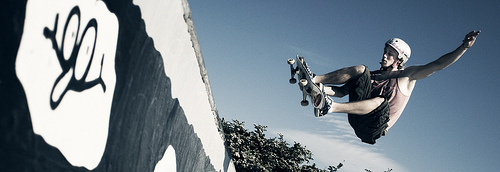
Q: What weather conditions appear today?
A: It is clear.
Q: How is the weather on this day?
A: It is clear.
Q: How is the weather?
A: It is clear.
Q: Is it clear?
A: Yes, it is clear.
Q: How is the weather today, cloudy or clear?
A: It is clear.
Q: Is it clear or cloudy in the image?
A: It is clear.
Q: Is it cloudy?
A: No, it is clear.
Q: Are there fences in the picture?
A: No, there are no fences.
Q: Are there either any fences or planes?
A: No, there are no fences or planes.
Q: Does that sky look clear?
A: Yes, the sky is clear.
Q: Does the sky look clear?
A: Yes, the sky is clear.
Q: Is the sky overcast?
A: No, the sky is clear.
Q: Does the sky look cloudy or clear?
A: The sky is clear.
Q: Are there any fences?
A: No, there are no fences.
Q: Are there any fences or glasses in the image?
A: No, there are no fences or glasses.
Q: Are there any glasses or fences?
A: No, there are no fences or glasses.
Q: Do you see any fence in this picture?
A: No, there are no fences.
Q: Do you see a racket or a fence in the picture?
A: No, there are no fences or rackets.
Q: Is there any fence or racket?
A: No, there are no fences or rackets.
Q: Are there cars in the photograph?
A: No, there are no cars.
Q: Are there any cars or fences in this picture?
A: No, there are no cars or fences.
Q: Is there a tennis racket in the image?
A: No, there are no rackets.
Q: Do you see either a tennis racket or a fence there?
A: No, there are no rackets or fences.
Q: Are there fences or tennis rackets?
A: No, there are no tennis rackets or fences.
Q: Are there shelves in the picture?
A: No, there are no shelves.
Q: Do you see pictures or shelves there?
A: No, there are no shelves or pictures.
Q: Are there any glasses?
A: No, there are no glasses.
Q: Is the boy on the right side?
A: Yes, the boy is on the right of the image.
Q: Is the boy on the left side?
A: No, the boy is on the right of the image.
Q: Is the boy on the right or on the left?
A: The boy is on the right of the image.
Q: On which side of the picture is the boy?
A: The boy is on the right of the image.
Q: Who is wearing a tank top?
A: The boy is wearing a tank top.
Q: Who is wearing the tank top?
A: The boy is wearing a tank top.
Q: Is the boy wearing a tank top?
A: Yes, the boy is wearing a tank top.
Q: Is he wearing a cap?
A: No, the boy is wearing a tank top.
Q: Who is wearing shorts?
A: The boy is wearing shorts.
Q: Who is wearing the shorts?
A: The boy is wearing shorts.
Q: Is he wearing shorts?
A: Yes, the boy is wearing shorts.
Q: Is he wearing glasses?
A: No, the boy is wearing shorts.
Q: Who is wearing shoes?
A: The boy is wearing shoes.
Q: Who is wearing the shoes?
A: The boy is wearing shoes.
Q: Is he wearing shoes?
A: Yes, the boy is wearing shoes.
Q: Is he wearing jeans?
A: No, the boy is wearing shoes.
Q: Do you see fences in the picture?
A: No, there are no fences.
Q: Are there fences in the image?
A: No, there are no fences.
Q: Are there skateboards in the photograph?
A: Yes, there is a skateboard.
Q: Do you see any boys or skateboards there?
A: Yes, there is a skateboard.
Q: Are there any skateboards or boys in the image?
A: Yes, there is a skateboard.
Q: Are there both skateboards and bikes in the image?
A: No, there is a skateboard but no bikes.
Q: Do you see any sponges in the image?
A: No, there are no sponges.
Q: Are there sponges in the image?
A: No, there are no sponges.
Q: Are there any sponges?
A: No, there are no sponges.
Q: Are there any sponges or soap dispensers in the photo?
A: No, there are no sponges or soap dispensers.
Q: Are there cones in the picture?
A: No, there are no cones.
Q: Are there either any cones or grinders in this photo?
A: No, there are no cones or grinders.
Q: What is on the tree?
A: The leaves are on the tree.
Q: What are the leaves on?
A: The leaves are on the tree.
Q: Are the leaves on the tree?
A: Yes, the leaves are on the tree.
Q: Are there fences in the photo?
A: No, there are no fences.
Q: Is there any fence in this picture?
A: No, there are no fences.